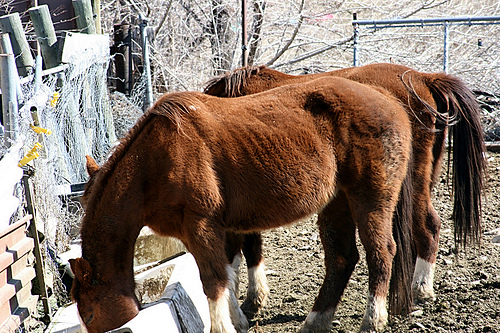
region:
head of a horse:
[65, 249, 133, 330]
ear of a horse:
[58, 255, 91, 283]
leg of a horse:
[180, 248, 238, 326]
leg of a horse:
[292, 225, 353, 328]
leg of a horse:
[352, 212, 416, 331]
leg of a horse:
[242, 249, 283, 331]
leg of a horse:
[411, 225, 451, 321]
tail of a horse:
[377, 192, 434, 329]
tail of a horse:
[430, 76, 491, 262]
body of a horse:
[182, 93, 419, 218]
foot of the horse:
[413, 238, 435, 296]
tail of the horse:
[435, 73, 485, 248]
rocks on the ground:
[279, 253, 301, 307]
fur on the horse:
[225, 136, 306, 213]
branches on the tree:
[240, 16, 329, 60]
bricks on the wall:
[1, 245, 27, 320]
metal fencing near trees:
[350, 14, 462, 51]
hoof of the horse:
[415, 279, 443, 304]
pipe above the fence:
[7, 3, 72, 55]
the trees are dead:
[223, 34, 320, 75]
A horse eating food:
[63, 71, 414, 331]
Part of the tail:
[451, 95, 481, 142]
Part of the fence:
[418, 20, 463, 36]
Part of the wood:
[31, 10, 53, 28]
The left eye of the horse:
[80, 310, 97, 325]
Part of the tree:
[263, 12, 285, 30]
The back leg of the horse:
[346, 173, 401, 332]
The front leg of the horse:
[181, 220, 240, 332]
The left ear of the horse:
[71, 255, 95, 285]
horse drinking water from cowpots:
[66, 66, 464, 331]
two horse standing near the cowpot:
[105, 54, 499, 331]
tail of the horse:
[440, 67, 485, 247]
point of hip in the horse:
[316, 78, 378, 125]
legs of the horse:
[326, 203, 413, 320]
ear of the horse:
[63, 249, 95, 288]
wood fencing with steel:
[12, 9, 83, 150]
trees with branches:
[156, 7, 394, 58]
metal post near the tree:
[341, 5, 498, 43]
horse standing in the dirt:
[207, 165, 447, 325]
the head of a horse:
[71, 226, 193, 318]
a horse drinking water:
[80, 76, 452, 304]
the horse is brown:
[61, 77, 417, 331]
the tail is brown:
[388, 145, 414, 320]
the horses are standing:
[71, 59, 493, 331]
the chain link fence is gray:
[2, 16, 499, 331]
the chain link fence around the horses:
[0, 15, 497, 332]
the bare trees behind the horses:
[1, 0, 499, 330]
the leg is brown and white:
[346, 170, 396, 332]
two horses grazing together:
[73, 65, 496, 329]